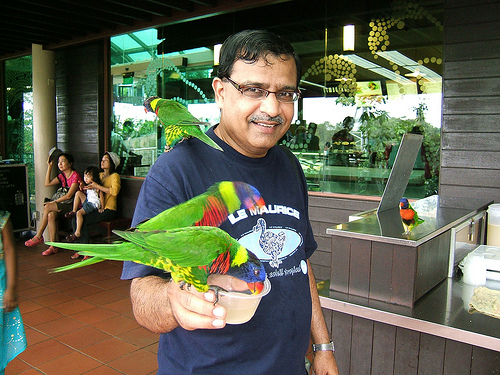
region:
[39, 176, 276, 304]
a pair of colorful birds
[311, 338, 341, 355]
a silver watch band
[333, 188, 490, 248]
a bird standing on a counter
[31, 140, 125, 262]
a family sitting on a bench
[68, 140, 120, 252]
a child sitting on an adults lap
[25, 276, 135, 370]
a red tile floor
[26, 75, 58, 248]
a thick white pole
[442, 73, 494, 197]
some dark brown siding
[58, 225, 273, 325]
a bird drinking out of a mans hand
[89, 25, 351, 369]
a man covered in birds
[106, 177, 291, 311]
two parrots on a man's hand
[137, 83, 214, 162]
a green parrot on a man's shoulder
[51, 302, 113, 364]
brown tiles of the ground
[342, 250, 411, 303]
black painted wood of the counter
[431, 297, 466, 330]
black surface of the counter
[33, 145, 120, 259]
women sitting on a bench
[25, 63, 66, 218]
white pillar of a building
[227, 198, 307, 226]
white lettering on a blue shirt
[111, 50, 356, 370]
a man with three birds on his body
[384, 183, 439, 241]
a parrot standing on a counter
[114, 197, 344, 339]
Two birds in a man hand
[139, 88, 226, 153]
Bird on a man shoulder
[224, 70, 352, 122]
Man wearing glasses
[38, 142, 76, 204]
Woman sitting on a bench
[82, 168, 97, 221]
Child sitting on a woman lap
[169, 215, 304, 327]
Man wearing a blue shirt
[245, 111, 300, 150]
Man with a grey mustache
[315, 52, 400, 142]
logo on a window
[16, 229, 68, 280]
woman wearing pink sandals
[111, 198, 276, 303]
Man holding two birds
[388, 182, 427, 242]
Bird on a counter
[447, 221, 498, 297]
lunch tray on a counter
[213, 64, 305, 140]
man wearing glasses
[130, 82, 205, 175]
bird on a man shoulder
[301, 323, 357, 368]
man wearing a wrist watch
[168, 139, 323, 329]
man wearing a blue tee shirt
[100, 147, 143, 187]
woman wearing a hat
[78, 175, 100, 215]
child sitting on a woman lap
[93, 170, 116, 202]
woman wearing a yellow shirt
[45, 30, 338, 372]
Man is holding parrots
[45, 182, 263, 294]
Parrots are multi colored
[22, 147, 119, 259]
People sitting on bench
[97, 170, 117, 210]
The shirt is yellow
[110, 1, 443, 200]
A large glass window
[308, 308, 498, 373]
The boards are wood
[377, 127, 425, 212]
Clip board on counter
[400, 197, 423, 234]
Bird standing on counter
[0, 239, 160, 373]
Floor is made of tiles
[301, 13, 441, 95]
Yellow designs on window